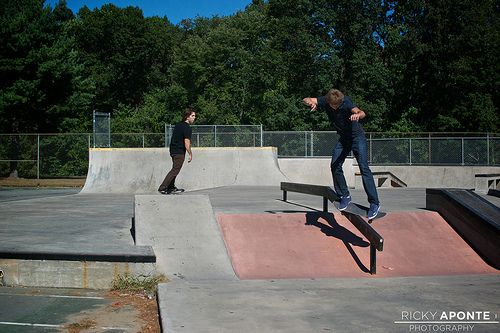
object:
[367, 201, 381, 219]
shoe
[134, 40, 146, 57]
trees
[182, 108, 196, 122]
hair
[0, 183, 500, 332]
ground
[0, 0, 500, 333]
skatepark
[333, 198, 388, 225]
skateboard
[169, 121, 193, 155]
shirt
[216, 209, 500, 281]
red paint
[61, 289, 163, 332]
dirt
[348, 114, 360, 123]
hand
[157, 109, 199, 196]
boy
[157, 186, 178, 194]
black shoes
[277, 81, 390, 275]
skate boarding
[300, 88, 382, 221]
boy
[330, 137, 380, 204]
jeans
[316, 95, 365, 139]
shirt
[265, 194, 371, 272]
shadow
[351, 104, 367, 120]
arm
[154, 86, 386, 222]
skateboarding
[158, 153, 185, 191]
pants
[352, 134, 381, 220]
leg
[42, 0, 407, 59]
sky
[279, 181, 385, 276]
railing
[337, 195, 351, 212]
shoe